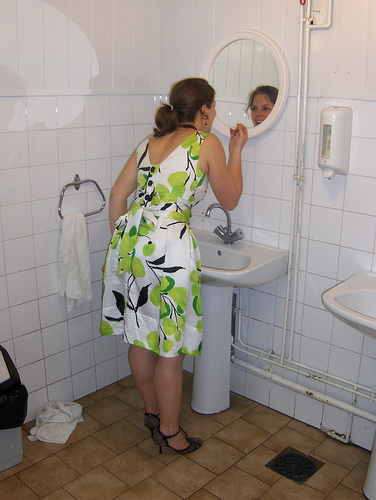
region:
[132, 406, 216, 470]
A ladies' black and gray shoes.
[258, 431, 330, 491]
A drain in the bathroom floor.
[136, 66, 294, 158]
A lady fixing her make up in the mirror.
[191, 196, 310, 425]
A bathroom sink in a public restroom.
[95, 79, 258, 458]
A lady in a party dress fixing something on her face.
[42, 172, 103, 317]
A towel holder with a towel on it.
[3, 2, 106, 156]
A really white spot on the wall.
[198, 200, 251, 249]
A silver sink fosit.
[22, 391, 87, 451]
A dirty towel on the floor.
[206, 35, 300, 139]
A mirror with a ladies reflection in it.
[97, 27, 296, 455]
Woman looking in mirror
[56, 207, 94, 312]
Towel hanging from rack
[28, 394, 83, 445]
Crumpled towel on the floor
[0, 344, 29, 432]
Black handbag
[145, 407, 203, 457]
High-heeled shoes on woman's feet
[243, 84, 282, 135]
Woman's face reflected in mirror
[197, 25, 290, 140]
Round mirror with white frame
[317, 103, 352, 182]
Soap dispenser on the wall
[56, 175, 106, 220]
Chrome towel holder on the wall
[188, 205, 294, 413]
White porcelain sink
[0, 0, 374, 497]
woman in small, messy [but not filthy] public restroom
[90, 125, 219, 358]
mid-length party dress w/ green leaves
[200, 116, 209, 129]
dangling amber colour earrings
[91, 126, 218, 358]
dress is cut in a retro-50s style [it isnt actually old]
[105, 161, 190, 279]
three buttons, one bow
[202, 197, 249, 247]
a somewhat interestingly constructed faucetq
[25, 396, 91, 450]
towel on the ground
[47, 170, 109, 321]
towel matching towel on the ground on silver metal towel hanger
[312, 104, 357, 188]
public restroom liquid soap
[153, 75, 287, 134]
lipstick, it's being checked by its wearer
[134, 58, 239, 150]
a woman wearing a ponytail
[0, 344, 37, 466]
a black trash can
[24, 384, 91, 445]
white towels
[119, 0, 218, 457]
a woman wearing black heels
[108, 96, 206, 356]
a woman wearing a dress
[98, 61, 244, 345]
a woman wearing a flowered dress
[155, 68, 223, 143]
a woman wearing earrings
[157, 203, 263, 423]
a white sink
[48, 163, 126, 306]
a metal towel rack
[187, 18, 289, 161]
a white mirror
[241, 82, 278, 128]
womans reflection in a restroom mirror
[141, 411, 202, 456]
black short heel shoes on a woman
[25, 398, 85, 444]
white towel on a brown restroom floor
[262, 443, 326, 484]
square drain on a bathroom floor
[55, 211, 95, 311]
white towel hanging from a rack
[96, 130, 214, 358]
white dress with a green and black design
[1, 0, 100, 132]
shadow on a white wall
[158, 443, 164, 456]
black shoe heel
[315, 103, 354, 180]
white soap dispenser on a wall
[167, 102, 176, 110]
pink ponytail holder on a woman's hair